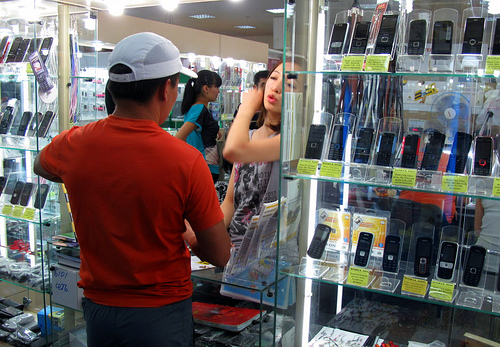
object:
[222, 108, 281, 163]
arm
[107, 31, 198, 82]
cap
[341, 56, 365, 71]
label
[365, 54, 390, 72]
label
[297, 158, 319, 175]
label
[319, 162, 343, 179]
label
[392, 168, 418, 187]
label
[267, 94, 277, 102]
lipstick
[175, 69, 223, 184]
woman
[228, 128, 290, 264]
shirt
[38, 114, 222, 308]
red shirt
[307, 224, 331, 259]
cellphone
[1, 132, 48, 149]
shelf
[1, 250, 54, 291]
shelf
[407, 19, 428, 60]
cellphone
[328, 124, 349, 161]
cellphone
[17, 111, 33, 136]
cellphone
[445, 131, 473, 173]
cellphone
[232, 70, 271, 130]
man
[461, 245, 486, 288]
cellphones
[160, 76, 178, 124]
head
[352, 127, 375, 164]
phone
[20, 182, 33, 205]
phone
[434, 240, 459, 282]
phone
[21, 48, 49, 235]
case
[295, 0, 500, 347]
case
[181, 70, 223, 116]
hair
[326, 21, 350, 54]
cell phones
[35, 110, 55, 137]
cell phones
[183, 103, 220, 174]
shirt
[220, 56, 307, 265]
she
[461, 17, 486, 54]
cellphone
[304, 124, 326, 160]
phone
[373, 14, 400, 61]
phone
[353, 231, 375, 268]
phone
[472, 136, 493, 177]
phone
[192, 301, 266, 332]
book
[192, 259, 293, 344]
counter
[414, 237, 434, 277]
phone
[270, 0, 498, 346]
display case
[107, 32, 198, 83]
hat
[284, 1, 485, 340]
case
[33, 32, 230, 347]
man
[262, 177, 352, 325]
case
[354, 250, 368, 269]
keyboards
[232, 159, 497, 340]
these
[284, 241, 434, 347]
case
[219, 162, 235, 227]
shoulder